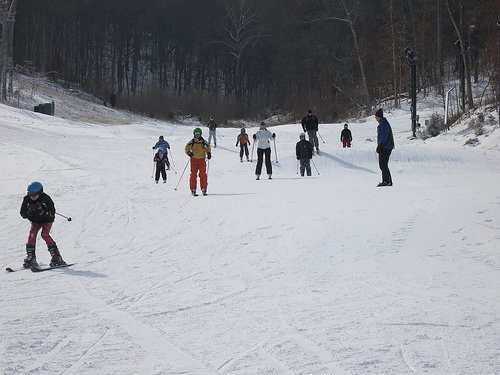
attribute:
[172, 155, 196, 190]
ski pole — metal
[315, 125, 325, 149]
ski pole — metal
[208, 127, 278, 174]
pole — metal 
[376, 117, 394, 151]
jacket — blue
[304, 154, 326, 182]
ski pole — metal 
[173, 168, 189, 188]
ski pole — metal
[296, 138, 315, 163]
jacket — black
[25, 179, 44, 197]
helmet — blue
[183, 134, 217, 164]
coat — yellow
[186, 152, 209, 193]
pants — orange